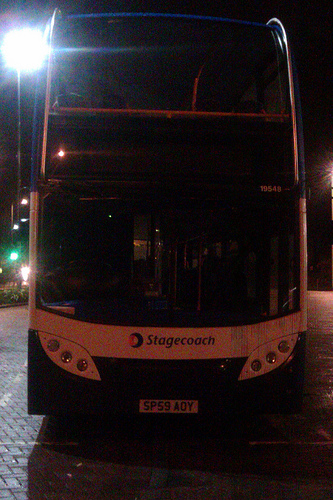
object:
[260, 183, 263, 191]
number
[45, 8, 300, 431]
front of bus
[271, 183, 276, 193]
number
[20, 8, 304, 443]
bus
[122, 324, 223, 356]
design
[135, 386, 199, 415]
license plate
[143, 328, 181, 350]
stage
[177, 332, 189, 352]
word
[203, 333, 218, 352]
word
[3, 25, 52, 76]
light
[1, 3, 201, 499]
left side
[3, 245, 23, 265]
light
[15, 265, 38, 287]
light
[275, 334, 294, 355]
light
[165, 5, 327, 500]
right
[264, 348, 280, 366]
light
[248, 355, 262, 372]
light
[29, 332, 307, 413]
paint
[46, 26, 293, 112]
window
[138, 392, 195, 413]
lettering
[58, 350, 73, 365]
light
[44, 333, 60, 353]
light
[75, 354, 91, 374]
light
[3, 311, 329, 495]
ground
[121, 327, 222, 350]
logo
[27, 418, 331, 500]
shadow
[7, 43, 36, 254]
pole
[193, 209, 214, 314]
pole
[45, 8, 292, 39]
roof